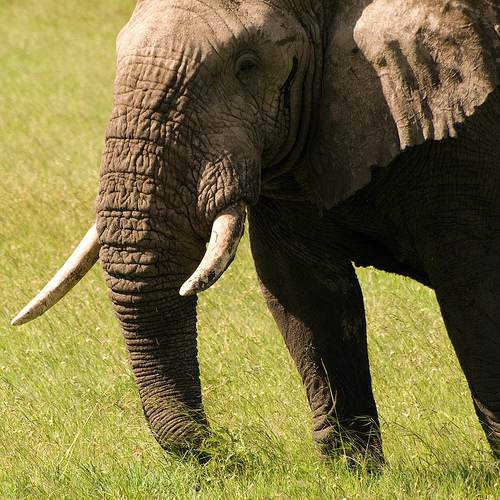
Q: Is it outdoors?
A: Yes, it is outdoors.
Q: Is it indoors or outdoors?
A: It is outdoors.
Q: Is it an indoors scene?
A: No, it is outdoors.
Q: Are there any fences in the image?
A: No, there are no fences.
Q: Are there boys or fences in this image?
A: No, there are no fences or boys.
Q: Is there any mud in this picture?
A: Yes, there is mud.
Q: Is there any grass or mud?
A: Yes, there is mud.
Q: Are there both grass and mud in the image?
A: Yes, there are both mud and grass.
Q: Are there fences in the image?
A: No, there are no fences.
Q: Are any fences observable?
A: No, there are no fences.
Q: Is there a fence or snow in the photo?
A: No, there are no fences or snow.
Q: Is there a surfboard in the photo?
A: No, there are no surfboards.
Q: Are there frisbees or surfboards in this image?
A: No, there are no surfboards or frisbees.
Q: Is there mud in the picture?
A: Yes, there is mud.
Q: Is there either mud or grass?
A: Yes, there is mud.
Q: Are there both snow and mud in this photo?
A: No, there is mud but no snow.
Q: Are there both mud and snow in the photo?
A: No, there is mud but no snow.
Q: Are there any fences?
A: No, there are no fences.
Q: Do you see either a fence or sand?
A: No, there are no fences or sand.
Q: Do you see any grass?
A: Yes, there is grass.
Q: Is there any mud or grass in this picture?
A: Yes, there is grass.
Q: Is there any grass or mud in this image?
A: Yes, there is grass.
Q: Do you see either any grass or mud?
A: Yes, there is grass.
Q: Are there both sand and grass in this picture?
A: No, there is grass but no sand.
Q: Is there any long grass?
A: Yes, there is long grass.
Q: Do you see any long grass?
A: Yes, there is long grass.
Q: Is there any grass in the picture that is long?
A: Yes, there is long grass.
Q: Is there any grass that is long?
A: Yes, there is grass that is long.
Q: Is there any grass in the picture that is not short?
A: Yes, there is long grass.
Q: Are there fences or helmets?
A: No, there are no fences or helmets.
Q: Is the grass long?
A: Yes, the grass is long.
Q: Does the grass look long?
A: Yes, the grass is long.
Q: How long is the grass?
A: The grass is long.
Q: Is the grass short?
A: No, the grass is long.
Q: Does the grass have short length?
A: No, the grass is long.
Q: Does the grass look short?
A: No, the grass is long.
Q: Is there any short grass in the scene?
A: No, there is grass but it is long.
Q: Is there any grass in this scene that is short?
A: No, there is grass but it is long.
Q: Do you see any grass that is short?
A: No, there is grass but it is long.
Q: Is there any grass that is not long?
A: No, there is grass but it is long.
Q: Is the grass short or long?
A: The grass is long.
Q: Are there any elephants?
A: Yes, there is an elephant.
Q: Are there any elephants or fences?
A: Yes, there is an elephant.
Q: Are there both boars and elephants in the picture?
A: No, there is an elephant but no boars.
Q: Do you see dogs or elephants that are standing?
A: Yes, the elephant is standing.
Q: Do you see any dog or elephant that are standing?
A: Yes, the elephant is standing.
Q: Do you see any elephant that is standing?
A: Yes, there is an elephant that is standing.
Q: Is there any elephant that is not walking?
A: Yes, there is an elephant that is standing.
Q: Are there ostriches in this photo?
A: No, there are no ostriches.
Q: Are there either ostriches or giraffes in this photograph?
A: No, there are no ostriches or giraffes.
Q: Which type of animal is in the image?
A: The animal is an elephant.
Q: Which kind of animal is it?
A: The animal is an elephant.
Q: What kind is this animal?
A: This is an elephant.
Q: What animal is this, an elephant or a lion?
A: This is an elephant.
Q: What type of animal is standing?
A: The animal is an elephant.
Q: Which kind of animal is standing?
A: The animal is an elephant.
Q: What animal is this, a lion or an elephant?
A: This is an elephant.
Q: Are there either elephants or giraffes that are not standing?
A: No, there is an elephant but it is standing.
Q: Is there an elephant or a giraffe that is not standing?
A: No, there is an elephant but it is standing.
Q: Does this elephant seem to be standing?
A: Yes, the elephant is standing.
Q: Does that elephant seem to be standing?
A: Yes, the elephant is standing.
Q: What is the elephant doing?
A: The elephant is standing.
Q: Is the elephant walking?
A: No, the elephant is standing.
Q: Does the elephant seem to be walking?
A: No, the elephant is standing.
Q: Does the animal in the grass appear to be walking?
A: No, the elephant is standing.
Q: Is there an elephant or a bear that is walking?
A: No, there is an elephant but it is standing.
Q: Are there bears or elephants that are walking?
A: No, there is an elephant but it is standing.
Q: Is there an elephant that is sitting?
A: No, there is an elephant but it is standing.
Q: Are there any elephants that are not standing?
A: No, there is an elephant but it is standing.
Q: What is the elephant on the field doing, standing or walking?
A: The elephant is standing.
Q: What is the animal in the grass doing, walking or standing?
A: The elephant is standing.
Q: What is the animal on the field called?
A: The animal is an elephant.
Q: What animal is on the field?
A: The animal is an elephant.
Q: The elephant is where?
A: The elephant is on the field.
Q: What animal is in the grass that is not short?
A: The elephant is in the grass.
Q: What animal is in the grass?
A: The elephant is in the grass.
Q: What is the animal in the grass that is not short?
A: The animal is an elephant.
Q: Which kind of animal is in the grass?
A: The animal is an elephant.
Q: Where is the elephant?
A: The elephant is in the grass.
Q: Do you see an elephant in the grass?
A: Yes, there is an elephant in the grass.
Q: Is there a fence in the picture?
A: No, there are no fences.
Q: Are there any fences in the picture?
A: No, there are no fences.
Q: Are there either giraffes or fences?
A: No, there are no fences or giraffes.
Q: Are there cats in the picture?
A: No, there are no cats.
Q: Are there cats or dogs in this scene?
A: No, there are no cats or dogs.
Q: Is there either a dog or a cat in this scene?
A: No, there are no cats or dogs.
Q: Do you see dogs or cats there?
A: No, there are no cats or dogs.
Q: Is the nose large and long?
A: Yes, the nose is large and long.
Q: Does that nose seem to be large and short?
A: No, the nose is large but long.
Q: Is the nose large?
A: Yes, the nose is large.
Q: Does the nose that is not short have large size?
A: Yes, the nose is large.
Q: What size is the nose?
A: The nose is large.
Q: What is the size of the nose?
A: The nose is large.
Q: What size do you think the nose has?
A: The nose has large size.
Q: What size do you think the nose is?
A: The nose is large.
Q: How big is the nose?
A: The nose is large.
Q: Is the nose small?
A: No, the nose is large.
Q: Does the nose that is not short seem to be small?
A: No, the nose is large.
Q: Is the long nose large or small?
A: The nose is large.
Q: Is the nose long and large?
A: Yes, the nose is long and large.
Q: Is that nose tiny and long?
A: No, the nose is long but large.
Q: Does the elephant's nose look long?
A: Yes, the nose is long.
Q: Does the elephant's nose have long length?
A: Yes, the nose is long.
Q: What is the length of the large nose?
A: The nose is long.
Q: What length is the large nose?
A: The nose is long.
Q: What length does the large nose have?
A: The nose has long length.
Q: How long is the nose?
A: The nose is long.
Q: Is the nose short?
A: No, the nose is long.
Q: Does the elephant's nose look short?
A: No, the nose is long.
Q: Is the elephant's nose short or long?
A: The nose is long.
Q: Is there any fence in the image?
A: No, there are no fences.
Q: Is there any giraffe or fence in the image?
A: No, there are no fences or giraffes.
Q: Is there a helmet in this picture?
A: No, there are no helmets.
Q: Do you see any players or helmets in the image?
A: No, there are no helmets or players.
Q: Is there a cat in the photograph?
A: No, there are no cats.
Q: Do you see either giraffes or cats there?
A: No, there are no cats or giraffes.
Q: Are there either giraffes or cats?
A: No, there are no cats or giraffes.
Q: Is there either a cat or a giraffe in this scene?
A: No, there are no cats or giraffes.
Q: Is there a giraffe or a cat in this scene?
A: No, there are no cats or giraffes.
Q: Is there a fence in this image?
A: No, there are no fences.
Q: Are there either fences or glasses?
A: No, there are no fences or glasses.